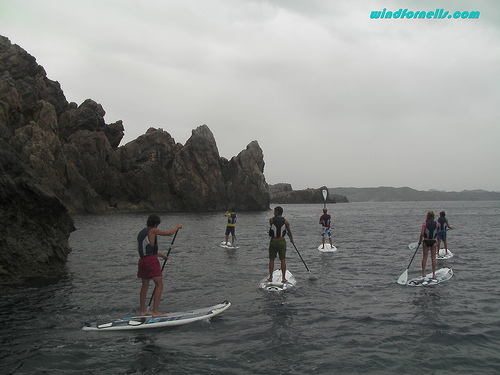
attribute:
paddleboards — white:
[128, 216, 498, 364]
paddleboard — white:
[315, 237, 337, 254]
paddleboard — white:
[260, 268, 297, 295]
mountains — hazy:
[347, 180, 479, 201]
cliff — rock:
[231, 137, 268, 196]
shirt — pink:
[418, 217, 444, 247]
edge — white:
[102, 313, 217, 333]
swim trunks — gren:
[264, 239, 291, 259]